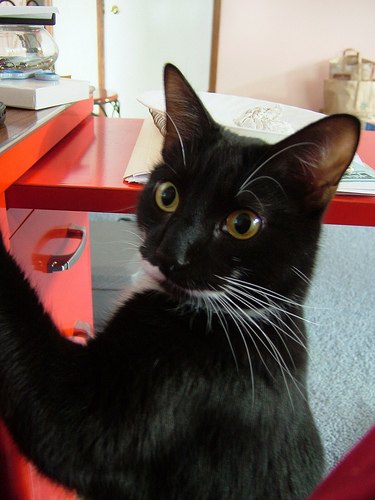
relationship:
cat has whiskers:
[0, 64, 360, 499] [185, 276, 340, 414]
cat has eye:
[0, 64, 360, 499] [224, 209, 262, 241]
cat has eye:
[0, 64, 360, 499] [152, 180, 179, 212]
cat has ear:
[0, 64, 360, 499] [288, 112, 361, 209]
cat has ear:
[0, 64, 360, 499] [163, 65, 214, 156]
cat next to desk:
[0, 64, 360, 499] [5, 115, 374, 230]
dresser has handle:
[0, 92, 94, 499] [51, 226, 88, 271]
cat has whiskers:
[0, 64, 360, 499] [120, 226, 145, 251]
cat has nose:
[0, 64, 360, 499] [159, 247, 186, 265]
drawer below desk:
[10, 211, 92, 498] [5, 115, 374, 230]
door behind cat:
[99, 2, 218, 121] [0, 64, 360, 499]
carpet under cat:
[93, 214, 374, 485] [0, 64, 360, 499]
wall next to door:
[216, 3, 374, 124] [99, 2, 218, 121]